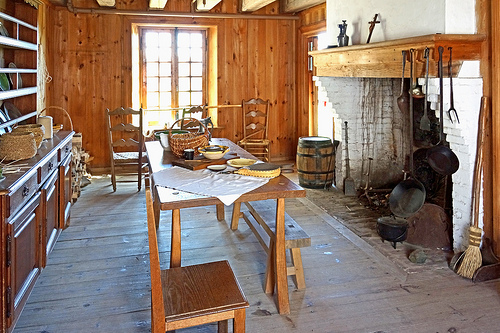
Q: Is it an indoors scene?
A: Yes, it is indoors.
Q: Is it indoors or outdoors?
A: It is indoors.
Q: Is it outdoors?
A: No, it is indoors.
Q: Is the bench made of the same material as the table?
A: Yes, both the bench and the table are made of wood.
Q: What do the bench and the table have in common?
A: The material, both the bench and the table are wooden.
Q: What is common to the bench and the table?
A: The material, both the bench and the table are wooden.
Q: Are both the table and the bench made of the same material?
A: Yes, both the table and the bench are made of wood.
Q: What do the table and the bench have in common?
A: The material, both the table and the bench are wooden.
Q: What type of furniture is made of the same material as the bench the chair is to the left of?
A: The table is made of the same material as the bench.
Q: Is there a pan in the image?
A: Yes, there is a pan.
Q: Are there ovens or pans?
A: Yes, there is a pan.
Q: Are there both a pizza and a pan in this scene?
A: No, there is a pan but no pizzas.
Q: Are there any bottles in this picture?
A: No, there are no bottles.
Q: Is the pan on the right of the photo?
A: Yes, the pan is on the right of the image.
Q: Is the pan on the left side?
A: No, the pan is on the right of the image.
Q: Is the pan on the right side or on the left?
A: The pan is on the right of the image.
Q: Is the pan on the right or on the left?
A: The pan is on the right of the image.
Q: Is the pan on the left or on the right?
A: The pan is on the right of the image.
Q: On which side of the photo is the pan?
A: The pan is on the right of the image.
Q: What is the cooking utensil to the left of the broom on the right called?
A: The cooking utensil is a pan.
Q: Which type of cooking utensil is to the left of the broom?
A: The cooking utensil is a pan.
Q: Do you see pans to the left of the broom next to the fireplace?
A: Yes, there is a pan to the left of the broom.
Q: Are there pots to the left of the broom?
A: No, there is a pan to the left of the broom.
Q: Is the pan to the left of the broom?
A: Yes, the pan is to the left of the broom.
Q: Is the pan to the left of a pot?
A: No, the pan is to the left of the broom.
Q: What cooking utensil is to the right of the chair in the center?
A: The cooking utensil is a pan.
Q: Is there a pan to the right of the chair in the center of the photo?
A: Yes, there is a pan to the right of the chair.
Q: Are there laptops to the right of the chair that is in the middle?
A: No, there is a pan to the right of the chair.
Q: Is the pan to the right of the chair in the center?
A: Yes, the pan is to the right of the chair.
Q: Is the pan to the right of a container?
A: No, the pan is to the right of the chair.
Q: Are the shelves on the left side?
A: Yes, the shelves are on the left of the image.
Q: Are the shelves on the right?
A: No, the shelves are on the left of the image.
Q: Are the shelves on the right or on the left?
A: The shelves are on the left of the image.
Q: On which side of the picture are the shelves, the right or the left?
A: The shelves are on the left of the image.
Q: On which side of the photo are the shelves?
A: The shelves are on the left of the image.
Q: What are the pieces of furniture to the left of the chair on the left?
A: The pieces of furniture are shelves.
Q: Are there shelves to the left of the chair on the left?
A: Yes, there are shelves to the left of the chair.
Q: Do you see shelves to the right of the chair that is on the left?
A: No, the shelves are to the left of the chair.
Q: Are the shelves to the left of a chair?
A: Yes, the shelves are to the left of a chair.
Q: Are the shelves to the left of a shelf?
A: No, the shelves are to the left of a chair.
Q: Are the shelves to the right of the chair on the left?
A: No, the shelves are to the left of the chair.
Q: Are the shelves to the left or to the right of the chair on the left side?
A: The shelves are to the left of the chair.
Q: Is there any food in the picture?
A: No, there is no food.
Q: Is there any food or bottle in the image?
A: No, there are no food or bottles.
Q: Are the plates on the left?
A: Yes, the plates are on the left of the image.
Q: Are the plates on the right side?
A: No, the plates are on the left of the image.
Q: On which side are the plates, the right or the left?
A: The plates are on the left of the image.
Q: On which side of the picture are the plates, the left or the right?
A: The plates are on the left of the image.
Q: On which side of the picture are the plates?
A: The plates are on the left of the image.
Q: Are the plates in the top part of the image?
A: Yes, the plates are in the top of the image.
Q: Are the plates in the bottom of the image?
A: No, the plates are in the top of the image.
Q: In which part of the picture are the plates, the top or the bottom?
A: The plates are in the top of the image.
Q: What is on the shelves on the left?
A: The plates are on the shelves.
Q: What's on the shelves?
A: The plates are on the shelves.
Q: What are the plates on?
A: The plates are on the shelves.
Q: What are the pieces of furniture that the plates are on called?
A: The pieces of furniture are shelves.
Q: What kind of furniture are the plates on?
A: The plates are on the shelves.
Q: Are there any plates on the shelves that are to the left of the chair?
A: Yes, there are plates on the shelves.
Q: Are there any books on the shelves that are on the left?
A: No, there are plates on the shelves.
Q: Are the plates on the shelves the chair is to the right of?
A: Yes, the plates are on the shelves.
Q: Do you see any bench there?
A: Yes, there is a bench.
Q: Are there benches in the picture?
A: Yes, there is a bench.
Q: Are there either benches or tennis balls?
A: Yes, there is a bench.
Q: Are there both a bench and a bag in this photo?
A: No, there is a bench but no bags.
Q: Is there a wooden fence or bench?
A: Yes, there is a wood bench.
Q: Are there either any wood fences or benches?
A: Yes, there is a wood bench.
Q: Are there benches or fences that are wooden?
A: Yes, the bench is wooden.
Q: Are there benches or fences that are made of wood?
A: Yes, the bench is made of wood.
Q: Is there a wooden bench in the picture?
A: Yes, there is a wood bench.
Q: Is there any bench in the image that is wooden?
A: Yes, there is a bench that is wooden.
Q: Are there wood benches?
A: Yes, there is a bench that is made of wood.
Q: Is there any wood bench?
A: Yes, there is a bench that is made of wood.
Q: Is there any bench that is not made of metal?
A: Yes, there is a bench that is made of wood.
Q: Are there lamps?
A: No, there are no lamps.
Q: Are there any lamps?
A: No, there are no lamps.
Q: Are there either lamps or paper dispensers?
A: No, there are no lamps or paper dispensers.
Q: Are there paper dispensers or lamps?
A: No, there are no lamps or paper dispensers.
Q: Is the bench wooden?
A: Yes, the bench is wooden.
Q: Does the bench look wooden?
A: Yes, the bench is wooden.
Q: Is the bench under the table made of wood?
A: Yes, the bench is made of wood.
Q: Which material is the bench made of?
A: The bench is made of wood.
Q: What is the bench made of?
A: The bench is made of wood.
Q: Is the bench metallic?
A: No, the bench is wooden.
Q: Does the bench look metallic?
A: No, the bench is wooden.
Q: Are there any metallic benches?
A: No, there is a bench but it is wooden.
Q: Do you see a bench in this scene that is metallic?
A: No, there is a bench but it is wooden.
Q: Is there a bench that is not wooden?
A: No, there is a bench but it is wooden.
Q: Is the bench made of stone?
A: No, the bench is made of wood.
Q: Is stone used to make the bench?
A: No, the bench is made of wood.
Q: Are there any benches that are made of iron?
A: No, there is a bench but it is made of wood.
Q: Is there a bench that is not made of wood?
A: No, there is a bench but it is made of wood.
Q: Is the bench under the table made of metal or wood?
A: The bench is made of wood.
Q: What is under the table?
A: The bench is under the table.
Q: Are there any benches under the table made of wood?
A: Yes, there is a bench under the table.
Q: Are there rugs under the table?
A: No, there is a bench under the table.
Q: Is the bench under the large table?
A: Yes, the bench is under the table.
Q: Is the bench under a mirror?
A: No, the bench is under the table.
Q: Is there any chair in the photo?
A: Yes, there is a chair.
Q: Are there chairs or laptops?
A: Yes, there is a chair.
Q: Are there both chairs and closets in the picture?
A: No, there is a chair but no closets.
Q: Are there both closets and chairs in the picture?
A: No, there is a chair but no closets.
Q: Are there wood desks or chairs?
A: Yes, there is a wood chair.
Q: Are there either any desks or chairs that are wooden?
A: Yes, the chair is wooden.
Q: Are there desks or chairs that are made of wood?
A: Yes, the chair is made of wood.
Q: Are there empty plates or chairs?
A: Yes, there is an empty chair.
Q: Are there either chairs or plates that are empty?
A: Yes, the chair is empty.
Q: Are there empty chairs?
A: Yes, there is an empty chair.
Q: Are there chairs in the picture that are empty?
A: Yes, there is a chair that is empty.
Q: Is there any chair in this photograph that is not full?
A: Yes, there is a empty chair.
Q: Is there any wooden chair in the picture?
A: Yes, there is a wood chair.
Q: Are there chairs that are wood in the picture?
A: Yes, there is a wood chair.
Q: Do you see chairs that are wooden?
A: Yes, there is a chair that is wooden.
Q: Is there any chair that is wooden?
A: Yes, there is a chair that is wooden.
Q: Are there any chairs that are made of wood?
A: Yes, there is a chair that is made of wood.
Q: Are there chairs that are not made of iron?
A: Yes, there is a chair that is made of wood.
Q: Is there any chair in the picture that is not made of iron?
A: Yes, there is a chair that is made of wood.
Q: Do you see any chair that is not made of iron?
A: Yes, there is a chair that is made of wood.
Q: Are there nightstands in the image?
A: No, there are no nightstands.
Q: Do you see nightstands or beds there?
A: No, there are no nightstands or beds.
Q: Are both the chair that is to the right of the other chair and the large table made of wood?
A: Yes, both the chair and the table are made of wood.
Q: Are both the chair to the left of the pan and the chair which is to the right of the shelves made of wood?
A: Yes, both the chair and the chair are made of wood.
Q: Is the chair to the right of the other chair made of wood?
A: Yes, the chair is made of wood.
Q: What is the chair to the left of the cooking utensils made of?
A: The chair is made of wood.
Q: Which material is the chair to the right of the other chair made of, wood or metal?
A: The chair is made of wood.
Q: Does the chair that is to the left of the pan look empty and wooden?
A: Yes, the chair is empty and wooden.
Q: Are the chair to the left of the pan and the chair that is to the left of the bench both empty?
A: Yes, both the chair and the chair are empty.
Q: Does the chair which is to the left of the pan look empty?
A: Yes, the chair is empty.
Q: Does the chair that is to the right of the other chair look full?
A: No, the chair is empty.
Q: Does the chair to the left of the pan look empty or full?
A: The chair is empty.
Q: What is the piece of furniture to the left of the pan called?
A: The piece of furniture is a chair.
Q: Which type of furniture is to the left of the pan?
A: The piece of furniture is a chair.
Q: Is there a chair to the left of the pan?
A: Yes, there is a chair to the left of the pan.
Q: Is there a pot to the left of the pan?
A: No, there is a chair to the left of the pan.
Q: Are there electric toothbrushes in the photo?
A: No, there are no electric toothbrushes.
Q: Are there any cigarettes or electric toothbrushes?
A: No, there are no electric toothbrushes or cigarettes.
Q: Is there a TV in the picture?
A: No, there are no televisions.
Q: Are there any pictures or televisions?
A: No, there are no televisions or pictures.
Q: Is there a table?
A: Yes, there is a table.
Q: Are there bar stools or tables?
A: Yes, there is a table.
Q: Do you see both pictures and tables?
A: No, there is a table but no pictures.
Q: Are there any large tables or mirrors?
A: Yes, there is a large table.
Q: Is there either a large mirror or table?
A: Yes, there is a large table.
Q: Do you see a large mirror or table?
A: Yes, there is a large table.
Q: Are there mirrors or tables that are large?
A: Yes, the table is large.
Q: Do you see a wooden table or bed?
A: Yes, there is a wood table.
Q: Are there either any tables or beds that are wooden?
A: Yes, the table is wooden.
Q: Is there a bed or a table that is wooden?
A: Yes, the table is wooden.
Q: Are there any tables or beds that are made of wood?
A: Yes, the table is made of wood.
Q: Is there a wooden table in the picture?
A: Yes, there is a wood table.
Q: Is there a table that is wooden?
A: Yes, there is a table that is wooden.